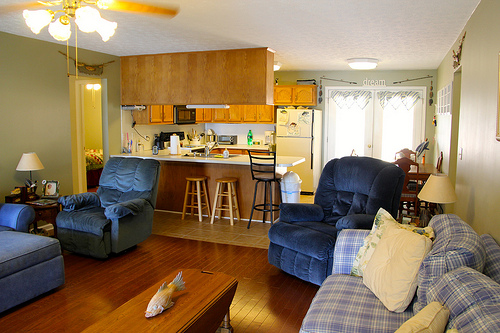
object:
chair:
[270, 150, 397, 283]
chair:
[56, 154, 158, 258]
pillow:
[356, 233, 427, 312]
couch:
[307, 211, 498, 331]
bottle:
[247, 130, 254, 145]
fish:
[146, 271, 189, 319]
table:
[83, 269, 243, 331]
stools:
[184, 176, 213, 221]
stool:
[245, 147, 283, 229]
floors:
[0, 227, 312, 332]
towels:
[169, 135, 181, 154]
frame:
[43, 180, 61, 199]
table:
[16, 199, 62, 235]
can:
[281, 172, 300, 204]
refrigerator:
[276, 110, 320, 192]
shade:
[15, 153, 43, 170]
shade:
[420, 175, 454, 205]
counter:
[211, 144, 270, 151]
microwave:
[175, 105, 195, 123]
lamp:
[17, 152, 44, 172]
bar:
[111, 154, 306, 167]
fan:
[5, 2, 181, 23]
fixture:
[20, 6, 117, 42]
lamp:
[414, 172, 453, 204]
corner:
[388, 155, 481, 244]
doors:
[325, 90, 425, 160]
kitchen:
[119, 42, 308, 212]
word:
[368, 79, 388, 88]